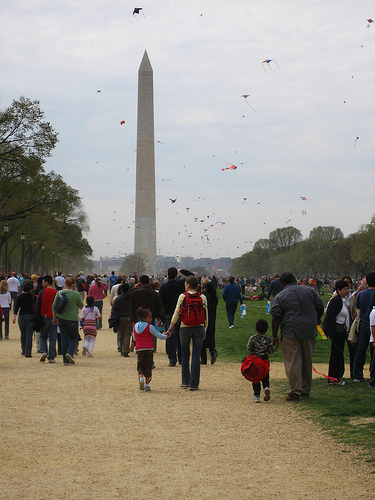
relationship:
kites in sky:
[165, 150, 264, 253] [168, 18, 263, 73]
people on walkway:
[19, 259, 142, 348] [24, 391, 222, 475]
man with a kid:
[269, 270, 330, 403] [235, 314, 279, 391]